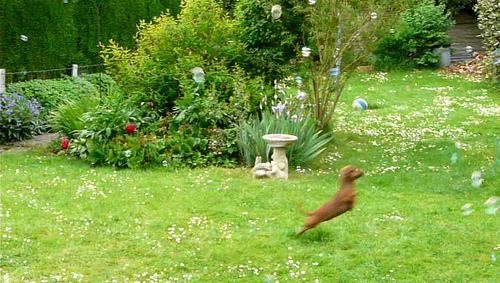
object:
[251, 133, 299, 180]
bird bath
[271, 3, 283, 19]
bubble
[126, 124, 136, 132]
blossom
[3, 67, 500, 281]
yard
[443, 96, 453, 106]
bubbles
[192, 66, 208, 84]
bubble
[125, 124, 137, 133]
red flower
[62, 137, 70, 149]
red flower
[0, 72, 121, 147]
bush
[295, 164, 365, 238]
dog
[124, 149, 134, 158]
bubbles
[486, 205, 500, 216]
bubbles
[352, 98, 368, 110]
ball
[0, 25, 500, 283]
floor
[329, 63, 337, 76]
bubble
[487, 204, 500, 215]
bubble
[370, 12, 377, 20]
bubble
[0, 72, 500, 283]
flowers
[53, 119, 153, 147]
two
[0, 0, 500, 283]
section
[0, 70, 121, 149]
row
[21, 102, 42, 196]
left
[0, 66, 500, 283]
grass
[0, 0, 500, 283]
garden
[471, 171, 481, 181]
bubble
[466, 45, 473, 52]
bubble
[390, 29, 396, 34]
bubble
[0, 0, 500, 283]
air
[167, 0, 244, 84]
leaves